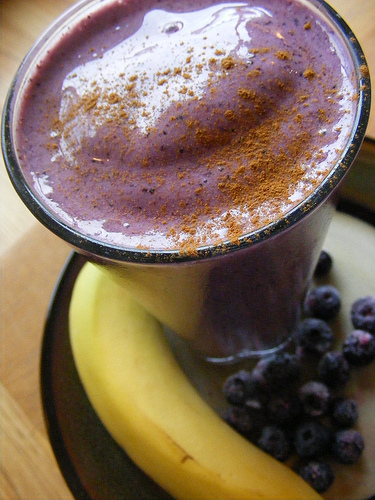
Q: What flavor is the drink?
A: Blueberry and banana.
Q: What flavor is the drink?
A: Blueberry and banana.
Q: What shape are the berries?
A: The berries are round.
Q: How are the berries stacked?
A: The berries are in a pile.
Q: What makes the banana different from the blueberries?
A: The banana is yellow.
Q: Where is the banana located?
A: The banana is next to the blueberries.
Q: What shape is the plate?
A: The plate is round.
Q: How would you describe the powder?
A: The powder is brown.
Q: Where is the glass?
A: The glass is on a plate.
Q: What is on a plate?
A: Fruit on a plate.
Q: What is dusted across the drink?
A: Cinnamon.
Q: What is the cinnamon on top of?
A: A drink.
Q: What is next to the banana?
A: A pile of blueberries.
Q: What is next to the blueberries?
A: A banana.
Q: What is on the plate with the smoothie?
A: Fruit.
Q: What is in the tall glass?
A: A fruit smoothy.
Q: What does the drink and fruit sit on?
A: An earth colored plate.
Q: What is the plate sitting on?
A: A light colored wood table.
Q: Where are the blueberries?
A: On the plate.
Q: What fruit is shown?
A: A banana abd blueberries.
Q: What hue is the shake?
A: Purple.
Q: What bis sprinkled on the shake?
A: Cinnnamin.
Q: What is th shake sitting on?
A: Cutting board.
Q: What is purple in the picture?
A: Blueberries.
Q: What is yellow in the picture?
A: Banana.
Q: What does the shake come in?
A: A glass.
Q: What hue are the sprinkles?
A: Brown.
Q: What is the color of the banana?
A: Yellow.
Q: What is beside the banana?
A: A cup.